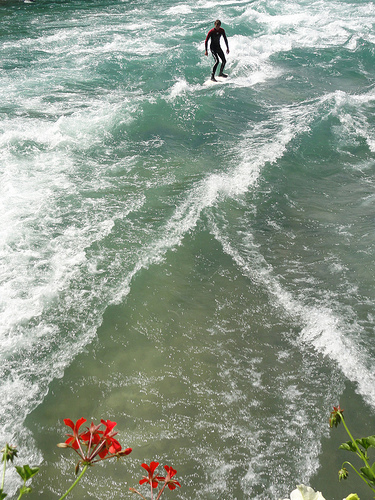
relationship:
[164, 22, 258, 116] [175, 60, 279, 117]
man on surfboard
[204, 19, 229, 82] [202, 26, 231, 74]
man wears wet suit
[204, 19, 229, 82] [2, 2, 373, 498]
man in water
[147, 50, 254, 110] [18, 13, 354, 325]
surfboard in water